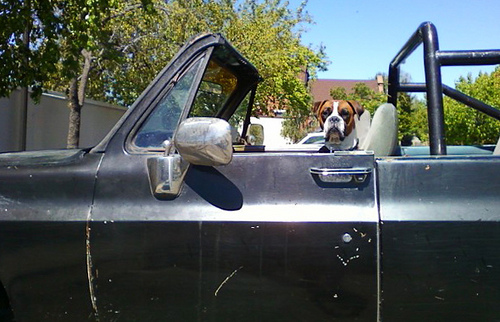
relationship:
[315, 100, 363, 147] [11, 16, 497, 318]
dog in car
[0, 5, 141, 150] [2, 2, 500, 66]
tree in background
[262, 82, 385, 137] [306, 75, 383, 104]
building has a roof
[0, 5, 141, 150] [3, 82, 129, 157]
tree near wall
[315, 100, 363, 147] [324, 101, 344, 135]
dog has stripe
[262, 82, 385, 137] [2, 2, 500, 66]
house in background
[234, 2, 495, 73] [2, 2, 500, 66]
sky in background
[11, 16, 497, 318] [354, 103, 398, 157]
car has seats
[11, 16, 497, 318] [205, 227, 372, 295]
car has scratches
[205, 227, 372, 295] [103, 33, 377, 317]
scratches are on door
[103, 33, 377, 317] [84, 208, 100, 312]
door has rust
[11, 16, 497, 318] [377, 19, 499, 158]
car has roll bars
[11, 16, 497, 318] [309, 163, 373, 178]
car has handle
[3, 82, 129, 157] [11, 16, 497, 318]
wall behind car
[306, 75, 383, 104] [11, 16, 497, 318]
roof behind car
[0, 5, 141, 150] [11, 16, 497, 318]
tree behind car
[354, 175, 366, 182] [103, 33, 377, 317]
key slot on door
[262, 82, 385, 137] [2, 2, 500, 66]
building in background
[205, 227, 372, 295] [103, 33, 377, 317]
scratches on door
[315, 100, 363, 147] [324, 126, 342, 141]
dog has jowls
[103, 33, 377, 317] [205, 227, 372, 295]
door has scratches